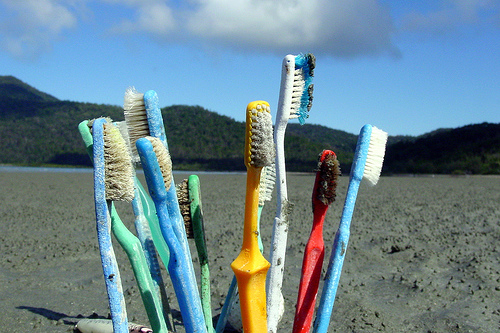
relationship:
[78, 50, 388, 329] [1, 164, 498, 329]
toothbrushes standing on beach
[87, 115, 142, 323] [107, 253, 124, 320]
toothbrush with speckles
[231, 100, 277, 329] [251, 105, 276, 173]
toothbrush with bristles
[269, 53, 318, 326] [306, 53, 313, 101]
toothbrush with sand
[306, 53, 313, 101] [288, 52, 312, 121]
sand on bristles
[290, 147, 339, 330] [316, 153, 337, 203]
toothbrush with bristles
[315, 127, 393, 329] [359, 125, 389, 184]
toothbrush with bristles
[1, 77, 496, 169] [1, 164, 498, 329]
hill near beach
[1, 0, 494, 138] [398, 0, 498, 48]
sky with clouds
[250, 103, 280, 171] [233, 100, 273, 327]
bristles on toothbrush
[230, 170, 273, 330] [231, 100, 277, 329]
handle on toothbrush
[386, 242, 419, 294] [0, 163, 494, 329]
rocks on sand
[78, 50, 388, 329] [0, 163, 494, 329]
toothbrushes in sand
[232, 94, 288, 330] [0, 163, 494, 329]
toothbrush in sand